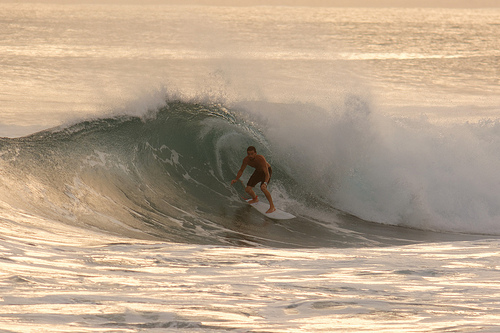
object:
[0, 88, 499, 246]
wave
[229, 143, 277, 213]
man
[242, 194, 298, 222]
board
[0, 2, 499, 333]
water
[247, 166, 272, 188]
shorts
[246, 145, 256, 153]
hair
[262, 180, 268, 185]
wristband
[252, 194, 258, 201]
rope